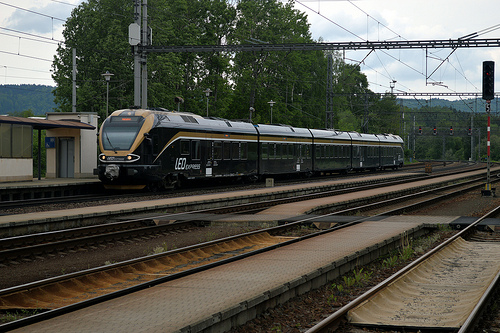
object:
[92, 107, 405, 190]
train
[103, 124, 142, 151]
windshield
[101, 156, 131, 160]
headlights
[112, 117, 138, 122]
sign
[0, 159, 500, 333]
tracks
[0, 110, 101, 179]
buildings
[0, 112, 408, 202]
train station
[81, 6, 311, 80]
leaves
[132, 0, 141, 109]
pole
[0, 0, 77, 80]
lines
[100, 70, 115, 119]
lamp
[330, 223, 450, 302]
grass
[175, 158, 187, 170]
word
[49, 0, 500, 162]
trees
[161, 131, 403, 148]
stripe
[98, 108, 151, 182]
front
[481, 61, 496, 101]
light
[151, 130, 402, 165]
stripes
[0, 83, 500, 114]
mountians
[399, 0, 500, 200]
back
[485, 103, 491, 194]
pole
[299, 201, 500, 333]
track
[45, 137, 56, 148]
sign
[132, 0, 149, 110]
poles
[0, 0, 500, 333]
air